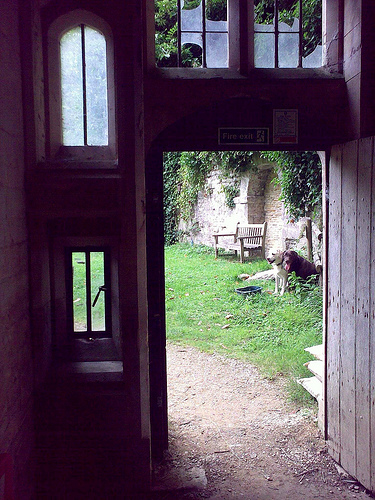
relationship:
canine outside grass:
[267, 249, 288, 296] [58, 241, 328, 402]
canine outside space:
[281, 248, 316, 282] [171, 247, 315, 365]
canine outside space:
[265, 249, 288, 296] [167, 238, 323, 359]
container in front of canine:
[238, 284, 264, 294] [279, 245, 324, 287]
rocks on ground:
[172, 465, 208, 494] [167, 372, 327, 496]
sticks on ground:
[291, 452, 320, 482] [167, 372, 327, 496]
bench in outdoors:
[210, 217, 275, 255] [163, 153, 324, 390]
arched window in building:
[46, 6, 123, 163] [1, 0, 374, 498]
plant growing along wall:
[161, 148, 328, 254] [165, 154, 312, 256]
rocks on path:
[172, 438, 362, 494] [74, 324, 372, 499]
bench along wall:
[212, 221, 268, 265] [166, 154, 320, 268]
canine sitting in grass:
[265, 249, 288, 296] [166, 241, 334, 373]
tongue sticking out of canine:
[284, 264, 290, 270] [265, 249, 288, 296]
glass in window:
[154, 0, 227, 68] [142, 1, 328, 72]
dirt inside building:
[166, 338, 371, 498] [1, 0, 374, 498]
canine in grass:
[282, 249, 317, 283] [216, 263, 315, 363]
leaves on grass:
[217, 309, 240, 330] [176, 251, 208, 307]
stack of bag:
[293, 339, 324, 406] [303, 338, 323, 363]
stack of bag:
[293, 339, 324, 406] [302, 356, 328, 382]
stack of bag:
[293, 339, 324, 406] [293, 370, 322, 400]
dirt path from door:
[176, 339, 277, 424] [325, 135, 374, 498]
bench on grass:
[212, 221, 268, 265] [58, 220, 328, 402]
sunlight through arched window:
[37, 20, 186, 221] [46, 6, 118, 162]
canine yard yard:
[265, 249, 288, 296] [170, 234, 332, 353]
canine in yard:
[265, 249, 288, 296] [152, 239, 326, 330]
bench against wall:
[212, 221, 268, 265] [170, 176, 336, 274]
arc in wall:
[238, 157, 293, 268] [165, 152, 321, 282]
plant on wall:
[161, 148, 324, 254] [167, 149, 327, 274]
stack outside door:
[295, 339, 324, 406] [154, 138, 338, 472]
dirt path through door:
[176, 339, 277, 424] [156, 116, 346, 420]